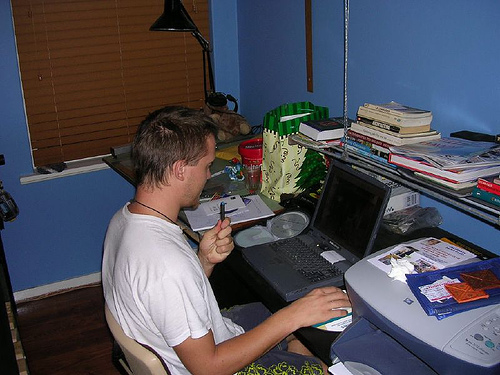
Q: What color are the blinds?
A: Brown.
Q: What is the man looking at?
A: Laptop.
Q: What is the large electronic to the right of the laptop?
A: Printer.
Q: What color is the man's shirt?
A: White.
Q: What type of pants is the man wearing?
A: Shorts.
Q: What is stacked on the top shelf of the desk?
A: Books.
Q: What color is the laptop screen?
A: Black.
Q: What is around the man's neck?
A: Necklace.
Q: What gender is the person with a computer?
A: A man.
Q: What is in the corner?
A: Lamp.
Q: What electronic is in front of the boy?
A: Laptop.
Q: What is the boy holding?
A: Pen.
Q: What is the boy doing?
A: Using the laptop?.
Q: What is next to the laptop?
A: Printer.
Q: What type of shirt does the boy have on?
A: White tank top.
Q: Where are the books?
A: On the wall shelf.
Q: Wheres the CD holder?
A: Next to the computer.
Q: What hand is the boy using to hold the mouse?
A: Right.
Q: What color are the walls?
A: Blue.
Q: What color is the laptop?
A: Gray and black.